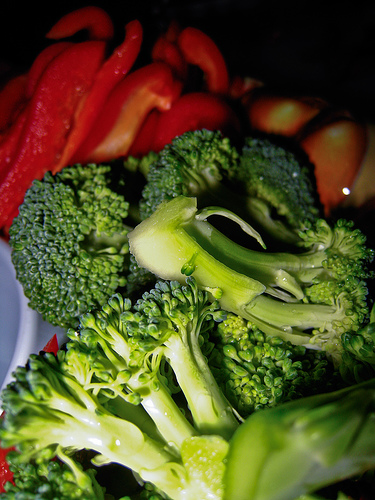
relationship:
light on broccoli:
[39, 331, 217, 500] [291, 204, 355, 269]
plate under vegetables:
[0, 236, 71, 391] [2, 4, 374, 498]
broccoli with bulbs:
[9, 174, 372, 470] [21, 227, 80, 283]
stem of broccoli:
[161, 331, 241, 444] [0, 127, 373, 498]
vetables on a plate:
[6, 130, 372, 499] [0, 232, 72, 420]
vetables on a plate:
[0, 6, 249, 249] [0, 232, 72, 420]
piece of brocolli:
[11, 158, 155, 329] [6, 162, 142, 323]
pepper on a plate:
[7, 6, 196, 164] [2, 238, 68, 388]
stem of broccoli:
[171, 349, 222, 402] [0, 127, 373, 498]